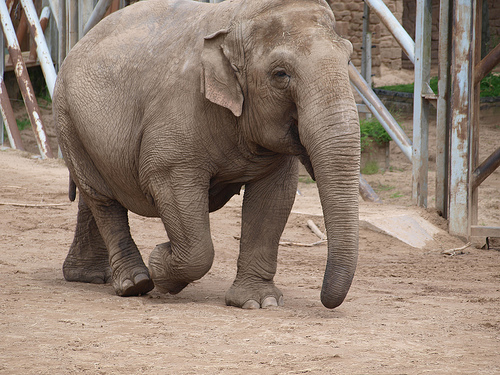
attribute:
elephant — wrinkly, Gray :
[52, 6, 372, 313]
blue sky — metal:
[427, 2, 451, 218]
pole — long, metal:
[446, 3, 497, 235]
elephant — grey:
[38, 2, 400, 315]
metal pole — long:
[448, 3, 480, 240]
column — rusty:
[448, 0, 480, 240]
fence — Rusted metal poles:
[3, 4, 73, 169]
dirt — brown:
[1, 100, 498, 372]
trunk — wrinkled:
[292, 63, 364, 313]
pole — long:
[427, 0, 468, 227]